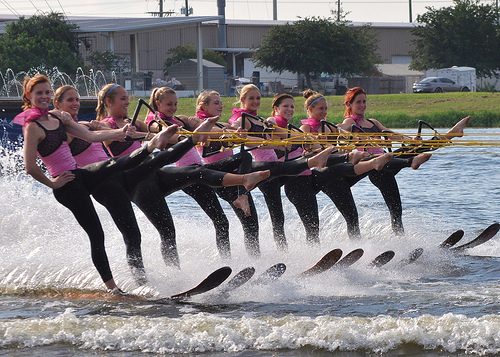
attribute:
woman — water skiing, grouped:
[15, 59, 478, 288]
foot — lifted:
[79, 110, 484, 197]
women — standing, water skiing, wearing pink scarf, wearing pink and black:
[12, 59, 486, 297]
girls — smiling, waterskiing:
[12, 59, 479, 277]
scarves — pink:
[17, 112, 377, 126]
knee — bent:
[184, 159, 214, 184]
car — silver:
[412, 72, 470, 95]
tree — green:
[250, 8, 391, 84]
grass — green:
[379, 92, 495, 113]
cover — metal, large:
[3, 13, 219, 94]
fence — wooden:
[346, 71, 423, 92]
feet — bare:
[138, 112, 468, 178]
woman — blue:
[291, 89, 423, 273]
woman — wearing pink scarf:
[18, 71, 58, 187]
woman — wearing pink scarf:
[333, 84, 385, 139]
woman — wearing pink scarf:
[227, 78, 267, 134]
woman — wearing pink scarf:
[96, 80, 139, 124]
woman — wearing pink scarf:
[297, 84, 335, 134]